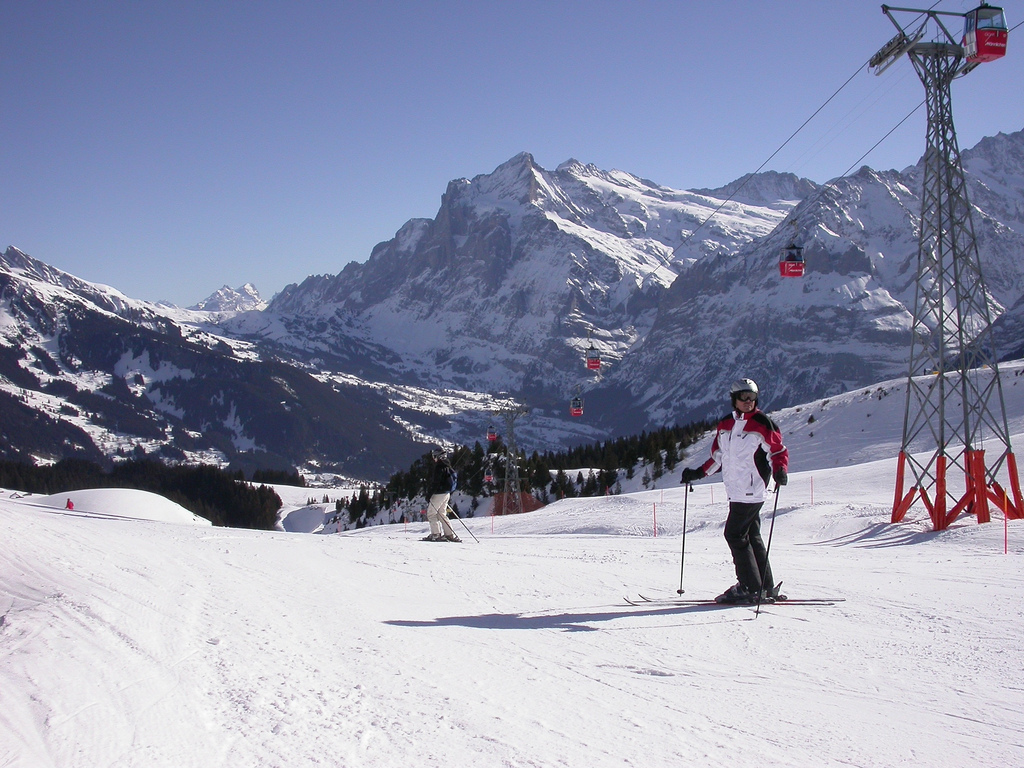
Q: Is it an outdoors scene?
A: Yes, it is outdoors.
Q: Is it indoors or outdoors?
A: It is outdoors.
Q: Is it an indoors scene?
A: No, it is outdoors.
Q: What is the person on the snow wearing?
A: The person is wearing a jacket.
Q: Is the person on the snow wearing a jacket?
A: Yes, the person is wearing a jacket.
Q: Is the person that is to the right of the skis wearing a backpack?
A: No, the person is wearing a jacket.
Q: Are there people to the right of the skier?
A: Yes, there is a person to the right of the skier.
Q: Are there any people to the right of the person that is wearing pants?
A: Yes, there is a person to the right of the skier.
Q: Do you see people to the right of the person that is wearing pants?
A: Yes, there is a person to the right of the skier.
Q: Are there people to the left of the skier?
A: No, the person is to the right of the skier.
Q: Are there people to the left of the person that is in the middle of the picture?
A: No, the person is to the right of the skier.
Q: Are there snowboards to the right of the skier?
A: No, there is a person to the right of the skier.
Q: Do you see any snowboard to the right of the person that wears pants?
A: No, there is a person to the right of the skier.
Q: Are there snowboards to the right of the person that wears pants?
A: No, there is a person to the right of the skier.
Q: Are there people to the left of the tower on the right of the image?
A: Yes, there is a person to the left of the tower.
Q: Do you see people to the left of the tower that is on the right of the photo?
A: Yes, there is a person to the left of the tower.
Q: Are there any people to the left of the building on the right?
A: Yes, there is a person to the left of the tower.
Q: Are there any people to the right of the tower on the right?
A: No, the person is to the left of the tower.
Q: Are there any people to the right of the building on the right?
A: No, the person is to the left of the tower.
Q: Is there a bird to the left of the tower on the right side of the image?
A: No, there is a person to the left of the tower.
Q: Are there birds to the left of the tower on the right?
A: No, there is a person to the left of the tower.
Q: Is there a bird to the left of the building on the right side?
A: No, there is a person to the left of the tower.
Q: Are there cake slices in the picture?
A: No, there are no cake slices.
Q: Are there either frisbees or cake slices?
A: No, there are no cake slices or frisbees.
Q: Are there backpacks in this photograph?
A: No, there are no backpacks.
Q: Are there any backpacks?
A: No, there are no backpacks.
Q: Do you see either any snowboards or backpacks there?
A: No, there are no backpacks or snowboards.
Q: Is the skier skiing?
A: Yes, the skier is skiing.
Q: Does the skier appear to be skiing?
A: Yes, the skier is skiing.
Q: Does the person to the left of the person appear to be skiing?
A: Yes, the skier is skiing.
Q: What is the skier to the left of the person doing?
A: The skier is skiing.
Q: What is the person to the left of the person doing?
A: The skier is skiing.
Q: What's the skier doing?
A: The skier is skiing.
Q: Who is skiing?
A: The skier is skiing.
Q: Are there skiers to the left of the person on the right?
A: Yes, there is a skier to the left of the person.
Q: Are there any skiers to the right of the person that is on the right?
A: No, the skier is to the left of the person.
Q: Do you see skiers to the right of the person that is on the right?
A: No, the skier is to the left of the person.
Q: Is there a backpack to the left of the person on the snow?
A: No, there is a skier to the left of the person.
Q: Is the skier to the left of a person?
A: Yes, the skier is to the left of a person.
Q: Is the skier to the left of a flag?
A: No, the skier is to the left of a person.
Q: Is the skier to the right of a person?
A: No, the skier is to the left of a person.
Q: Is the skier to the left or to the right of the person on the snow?
A: The skier is to the left of the person.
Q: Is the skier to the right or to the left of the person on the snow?
A: The skier is to the left of the person.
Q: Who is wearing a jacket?
A: The skier is wearing a jacket.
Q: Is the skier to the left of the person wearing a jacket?
A: Yes, the skier is wearing a jacket.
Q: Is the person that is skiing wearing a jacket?
A: Yes, the skier is wearing a jacket.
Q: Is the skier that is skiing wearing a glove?
A: No, the skier is wearing a jacket.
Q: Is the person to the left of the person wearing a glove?
A: No, the skier is wearing a jacket.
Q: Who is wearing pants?
A: The skier is wearing pants.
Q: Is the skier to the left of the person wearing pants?
A: Yes, the skier is wearing pants.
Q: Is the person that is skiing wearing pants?
A: Yes, the skier is wearing pants.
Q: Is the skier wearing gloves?
A: No, the skier is wearing pants.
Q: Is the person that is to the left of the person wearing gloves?
A: No, the skier is wearing pants.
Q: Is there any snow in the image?
A: Yes, there is snow.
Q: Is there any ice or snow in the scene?
A: Yes, there is snow.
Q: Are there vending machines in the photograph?
A: No, there are no vending machines.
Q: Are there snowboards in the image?
A: No, there are no snowboards.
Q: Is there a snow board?
A: No, there are no snowboards.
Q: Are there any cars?
A: No, there are no cars.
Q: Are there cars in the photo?
A: No, there are no cars.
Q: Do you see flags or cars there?
A: No, there are no cars or flags.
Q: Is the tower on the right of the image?
A: Yes, the tower is on the right of the image.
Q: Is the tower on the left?
A: No, the tower is on the right of the image.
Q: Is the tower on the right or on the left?
A: The tower is on the right of the image.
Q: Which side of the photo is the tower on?
A: The tower is on the right of the image.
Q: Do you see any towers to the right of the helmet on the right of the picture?
A: Yes, there is a tower to the right of the helmet.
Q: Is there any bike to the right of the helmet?
A: No, there is a tower to the right of the helmet.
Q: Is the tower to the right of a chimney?
A: No, the tower is to the right of the helmet.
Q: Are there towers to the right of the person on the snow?
A: Yes, there is a tower to the right of the person.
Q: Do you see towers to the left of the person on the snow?
A: No, the tower is to the right of the person.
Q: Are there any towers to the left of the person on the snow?
A: No, the tower is to the right of the person.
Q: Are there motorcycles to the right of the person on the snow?
A: No, there is a tower to the right of the person.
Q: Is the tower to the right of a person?
A: Yes, the tower is to the right of a person.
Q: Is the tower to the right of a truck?
A: No, the tower is to the right of a person.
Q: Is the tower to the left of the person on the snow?
A: No, the tower is to the right of the person.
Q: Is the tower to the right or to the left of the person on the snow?
A: The tower is to the right of the person.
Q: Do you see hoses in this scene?
A: No, there are no hoses.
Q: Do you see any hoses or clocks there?
A: No, there are no hoses or clocks.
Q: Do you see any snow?
A: Yes, there is snow.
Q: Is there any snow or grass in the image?
A: Yes, there is snow.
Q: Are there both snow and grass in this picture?
A: No, there is snow but no grass.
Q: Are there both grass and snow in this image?
A: No, there is snow but no grass.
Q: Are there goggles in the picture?
A: No, there are no goggles.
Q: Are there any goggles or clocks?
A: No, there are no goggles or clocks.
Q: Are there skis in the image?
A: Yes, there are skis.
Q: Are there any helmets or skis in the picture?
A: Yes, there are skis.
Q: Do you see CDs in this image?
A: No, there are no cds.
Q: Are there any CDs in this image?
A: No, there are no cds.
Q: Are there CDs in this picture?
A: No, there are no cds.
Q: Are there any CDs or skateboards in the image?
A: No, there are no CDs or skateboards.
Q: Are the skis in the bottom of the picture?
A: Yes, the skis are in the bottom of the image.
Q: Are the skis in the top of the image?
A: No, the skis are in the bottom of the image.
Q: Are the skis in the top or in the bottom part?
A: The skis are in the bottom of the image.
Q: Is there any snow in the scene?
A: Yes, there is snow.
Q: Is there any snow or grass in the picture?
A: Yes, there is snow.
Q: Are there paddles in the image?
A: No, there are no paddles.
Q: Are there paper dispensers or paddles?
A: No, there are no paddles or paper dispensers.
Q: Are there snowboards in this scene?
A: No, there are no snowboards.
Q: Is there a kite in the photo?
A: No, there are no kites.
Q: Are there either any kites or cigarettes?
A: No, there are no kites or cigarettes.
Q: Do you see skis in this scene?
A: Yes, there are skis.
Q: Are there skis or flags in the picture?
A: Yes, there are skis.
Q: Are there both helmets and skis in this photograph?
A: Yes, there are both skis and a helmet.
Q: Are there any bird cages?
A: No, there are no bird cages.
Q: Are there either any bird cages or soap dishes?
A: No, there are no bird cages or soap dishes.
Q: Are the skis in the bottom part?
A: Yes, the skis are in the bottom of the image.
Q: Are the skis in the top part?
A: No, the skis are in the bottom of the image.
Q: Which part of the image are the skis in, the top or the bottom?
A: The skis are in the bottom of the image.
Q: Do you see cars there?
A: No, there are no cars.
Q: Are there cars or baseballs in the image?
A: No, there are no cars or baseballs.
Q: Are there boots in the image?
A: Yes, there are boots.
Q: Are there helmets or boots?
A: Yes, there are boots.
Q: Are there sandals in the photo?
A: No, there are no sandals.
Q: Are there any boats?
A: No, there are no boats.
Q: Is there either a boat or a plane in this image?
A: No, there are no boats or airplanes.